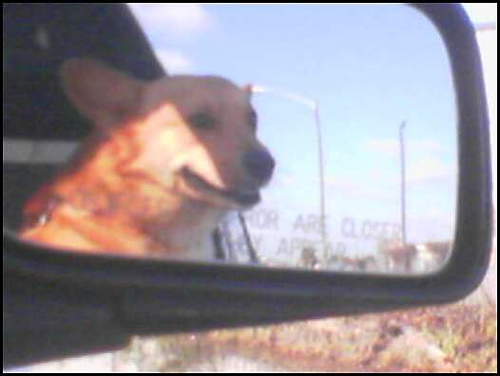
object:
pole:
[395, 122, 413, 245]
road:
[89, 350, 426, 372]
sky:
[126, 1, 499, 245]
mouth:
[180, 166, 267, 206]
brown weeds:
[124, 302, 494, 376]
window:
[2, 3, 221, 262]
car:
[0, 3, 499, 373]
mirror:
[0, 3, 494, 329]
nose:
[242, 144, 274, 181]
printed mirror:
[0, 183, 408, 274]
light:
[397, 111, 411, 248]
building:
[377, 240, 447, 272]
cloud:
[361, 136, 444, 155]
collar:
[12, 189, 141, 240]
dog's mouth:
[172, 160, 266, 212]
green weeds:
[440, 334, 465, 356]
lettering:
[57, 192, 411, 268]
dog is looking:
[12, 52, 275, 256]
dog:
[7, 51, 288, 256]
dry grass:
[218, 304, 496, 371]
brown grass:
[102, 304, 496, 372]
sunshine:
[128, 101, 224, 187]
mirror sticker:
[217, 208, 405, 266]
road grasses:
[110, 304, 498, 374]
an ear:
[54, 53, 145, 128]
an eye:
[179, 107, 220, 131]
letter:
[337, 213, 349, 234]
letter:
[291, 207, 305, 234]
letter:
[394, 217, 405, 245]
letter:
[243, 207, 398, 237]